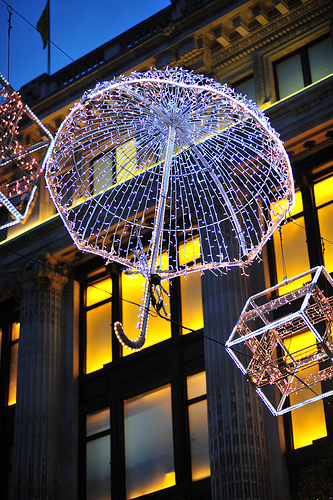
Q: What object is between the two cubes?
A: Umbrella.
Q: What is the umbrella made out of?
A: Lights.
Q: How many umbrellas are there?
A: One.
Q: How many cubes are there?
A: Two.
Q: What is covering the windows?
A: Shades.